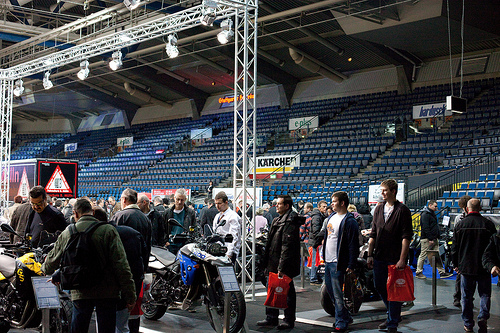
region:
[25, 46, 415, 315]
this is inside an arena dome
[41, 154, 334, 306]
this is a social gathering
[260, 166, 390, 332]
this are people in an arena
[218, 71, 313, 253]
this are metallic stands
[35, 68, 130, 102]
this are strong lights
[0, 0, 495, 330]
the interior of a stadium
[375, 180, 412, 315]
man carrying a red plastic bag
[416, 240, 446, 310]
a sign on a pole seen from behind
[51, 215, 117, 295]
dark backpack on person's back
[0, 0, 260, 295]
metal structure above people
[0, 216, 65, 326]
a motorcycle near a sign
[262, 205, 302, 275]
man wearing a dark jacket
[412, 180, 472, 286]
man walking near stadium seats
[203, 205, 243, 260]
man wearing a white jacket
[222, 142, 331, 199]
large sign among stadium seats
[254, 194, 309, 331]
man holding a red bag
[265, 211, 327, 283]
man wearing a dark jacket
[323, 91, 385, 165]
blue seats in the stadium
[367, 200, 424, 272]
man wearing a dark colored sweater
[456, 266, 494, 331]
man wearing blue jeans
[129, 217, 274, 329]
motorcycle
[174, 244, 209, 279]
blue portion of the motorcycle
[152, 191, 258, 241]
men looking at the motorcycles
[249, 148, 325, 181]
advertisement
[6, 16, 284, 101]
lights are pointing down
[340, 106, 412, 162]
the seats are blue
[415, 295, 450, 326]
shadow is cast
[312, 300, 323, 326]
the lines are white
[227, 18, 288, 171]
the stands are made of metal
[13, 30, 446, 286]
this is in a stadium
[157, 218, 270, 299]
the motorcycle is parked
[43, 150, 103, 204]
the sign is black and red in color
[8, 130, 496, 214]
the seats are blue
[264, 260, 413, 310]
the men carry red bags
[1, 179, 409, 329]
the men look at bikes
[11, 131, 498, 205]
the seats are empty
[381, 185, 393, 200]
the man is smiling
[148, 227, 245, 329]
the bike is blue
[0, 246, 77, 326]
the bike is yellow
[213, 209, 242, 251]
the man wears a white jacket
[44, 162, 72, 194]
the sign has a triangle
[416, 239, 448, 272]
man wears khakis